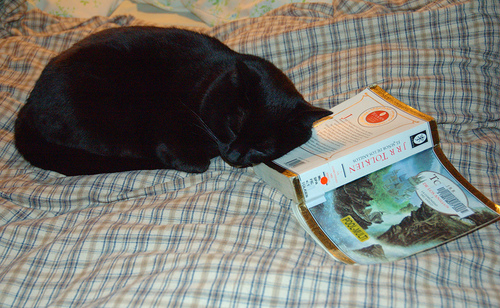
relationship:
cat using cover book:
[18, 15, 347, 170] [262, 84, 425, 174]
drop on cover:
[322, 178, 331, 189] [295, 144, 499, 267]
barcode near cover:
[285, 152, 306, 177] [295, 144, 499, 267]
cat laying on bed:
[14, 23, 332, 178] [4, 4, 497, 304]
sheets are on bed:
[3, 4, 498, 304] [4, 4, 497, 304]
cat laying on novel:
[14, 23, 332, 178] [254, 83, 498, 273]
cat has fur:
[18, 15, 347, 170] [41, 32, 220, 141]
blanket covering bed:
[9, 86, 362, 306] [4, 4, 497, 304]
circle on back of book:
[365, 106, 389, 123] [302, 66, 436, 228]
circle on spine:
[317, 170, 330, 184] [293, 123, 431, 195]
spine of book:
[293, 123, 431, 195] [302, 66, 436, 228]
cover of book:
[295, 144, 499, 267] [302, 66, 436, 228]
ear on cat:
[221, 52, 267, 94] [18, 15, 347, 170]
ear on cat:
[293, 98, 331, 125] [14, 23, 332, 178]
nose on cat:
[222, 141, 248, 166] [14, 23, 332, 178]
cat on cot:
[14, 23, 332, 178] [9, 3, 497, 306]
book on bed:
[302, 66, 436, 228] [12, 7, 472, 294]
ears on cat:
[230, 58, 340, 120] [11, 17, 333, 193]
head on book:
[197, 63, 348, 178] [302, 66, 436, 228]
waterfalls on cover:
[349, 171, 444, 223] [324, 120, 495, 265]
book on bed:
[302, 66, 436, 228] [4, 4, 497, 304]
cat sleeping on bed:
[14, 23, 332, 178] [4, 4, 497, 304]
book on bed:
[302, 66, 436, 228] [220, 1, 498, 118]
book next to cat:
[302, 66, 436, 228] [14, 23, 332, 178]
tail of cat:
[7, 102, 164, 177] [14, 23, 332, 178]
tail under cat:
[7, 102, 164, 177] [14, 23, 332, 178]